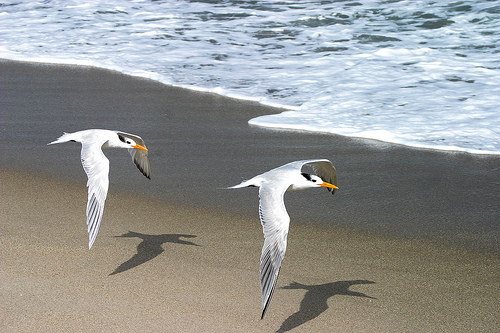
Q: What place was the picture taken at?
A: It was taken at the beach.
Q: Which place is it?
A: It is a beach.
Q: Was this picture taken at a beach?
A: Yes, it was taken in a beach.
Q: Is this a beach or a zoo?
A: It is a beach.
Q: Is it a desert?
A: No, it is a beach.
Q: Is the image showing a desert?
A: No, the picture is showing a beach.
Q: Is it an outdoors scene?
A: Yes, it is outdoors.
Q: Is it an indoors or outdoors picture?
A: It is outdoors.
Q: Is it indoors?
A: No, it is outdoors.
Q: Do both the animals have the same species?
A: Yes, all the animals are birds.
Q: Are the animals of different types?
A: No, all the animals are birds.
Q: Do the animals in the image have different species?
A: No, all the animals are birds.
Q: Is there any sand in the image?
A: Yes, there is sand.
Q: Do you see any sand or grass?
A: Yes, there is sand.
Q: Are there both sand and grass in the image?
A: No, there is sand but no grass.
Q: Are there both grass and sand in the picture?
A: No, there is sand but no grass.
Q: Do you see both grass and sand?
A: No, there is sand but no grass.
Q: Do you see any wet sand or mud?
A: Yes, there is wet sand.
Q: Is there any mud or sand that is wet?
A: Yes, the sand is wet.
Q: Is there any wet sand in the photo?
A: Yes, there is wet sand.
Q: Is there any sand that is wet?
A: Yes, there is sand that is wet.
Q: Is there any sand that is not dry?
A: Yes, there is wet sand.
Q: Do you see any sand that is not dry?
A: Yes, there is wet sand.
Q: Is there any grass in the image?
A: No, there is no grass.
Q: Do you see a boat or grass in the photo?
A: No, there are no grass or boats.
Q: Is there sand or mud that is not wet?
A: No, there is sand but it is wet.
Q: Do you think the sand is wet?
A: Yes, the sand is wet.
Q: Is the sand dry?
A: No, the sand is wet.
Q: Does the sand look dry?
A: No, the sand is wet.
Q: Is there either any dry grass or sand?
A: No, there is sand but it is wet.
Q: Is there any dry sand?
A: No, there is sand but it is wet.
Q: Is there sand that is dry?
A: No, there is sand but it is wet.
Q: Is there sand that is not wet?
A: No, there is sand but it is wet.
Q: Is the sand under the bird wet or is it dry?
A: The sand is wet.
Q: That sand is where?
A: The sand is on the beach.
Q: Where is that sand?
A: The sand is on the beach.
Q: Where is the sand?
A: The sand is on the beach.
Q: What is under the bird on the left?
A: The sand is under the bird.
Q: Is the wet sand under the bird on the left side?
A: Yes, the sand is under the bird.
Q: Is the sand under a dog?
A: No, the sand is under the bird.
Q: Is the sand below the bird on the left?
A: Yes, the sand is below the bird.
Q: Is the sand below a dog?
A: No, the sand is below the bird.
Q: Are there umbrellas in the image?
A: No, there are no umbrellas.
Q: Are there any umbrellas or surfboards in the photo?
A: No, there are no umbrellas or surfboards.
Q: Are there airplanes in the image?
A: No, there are no airplanes.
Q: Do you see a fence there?
A: No, there are no fences.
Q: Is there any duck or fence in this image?
A: No, there are no fences or ducks.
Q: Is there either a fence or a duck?
A: No, there are no fences or ducks.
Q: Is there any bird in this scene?
A: Yes, there is a bird.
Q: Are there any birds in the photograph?
A: Yes, there is a bird.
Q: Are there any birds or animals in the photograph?
A: Yes, there is a bird.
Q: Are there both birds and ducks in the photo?
A: No, there is a bird but no ducks.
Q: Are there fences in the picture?
A: No, there are no fences.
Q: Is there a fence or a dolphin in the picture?
A: No, there are no fences or dolphins.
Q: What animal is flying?
A: The animal is a bird.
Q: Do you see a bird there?
A: Yes, there is a bird.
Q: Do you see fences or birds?
A: Yes, there is a bird.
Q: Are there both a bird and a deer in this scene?
A: No, there is a bird but no deer.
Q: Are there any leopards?
A: No, there are no leopards.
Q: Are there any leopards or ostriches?
A: No, there are no leopards or ostriches.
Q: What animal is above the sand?
A: The animal is a bird.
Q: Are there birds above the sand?
A: Yes, there is a bird above the sand.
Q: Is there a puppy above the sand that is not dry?
A: No, there is a bird above the sand.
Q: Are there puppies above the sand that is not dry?
A: No, there is a bird above the sand.